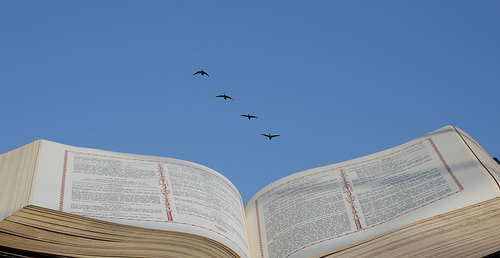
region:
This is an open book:
[1, 129, 496, 256]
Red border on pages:
[55, 140, 85, 222]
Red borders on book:
[52, 144, 467, 241]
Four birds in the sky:
[170, 58, 308, 173]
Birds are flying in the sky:
[182, 49, 293, 173]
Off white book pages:
[5, 140, 497, 257]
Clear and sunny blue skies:
[1, 0, 498, 192]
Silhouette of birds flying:
[195, 63, 305, 158]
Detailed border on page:
[155, 158, 187, 232]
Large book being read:
[6, 138, 498, 255]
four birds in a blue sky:
[63, 22, 400, 146]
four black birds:
[186, 56, 292, 151]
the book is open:
[2, 119, 498, 256]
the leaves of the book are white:
[1, 120, 498, 257]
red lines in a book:
[1, 120, 498, 255]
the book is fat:
[4, 121, 499, 256]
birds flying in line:
[191, 57, 282, 148]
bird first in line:
[189, 63, 213, 82]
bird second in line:
[209, 87, 237, 105]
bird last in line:
[256, 123, 281, 147]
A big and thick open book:
[0, 122, 498, 255]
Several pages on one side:
[320, 122, 497, 252]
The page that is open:
[26, 121, 496, 253]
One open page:
[27, 138, 249, 257]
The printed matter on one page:
[68, 152, 245, 248]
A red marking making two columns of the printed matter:
[156, 160, 171, 217]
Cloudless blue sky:
[0, 0, 497, 205]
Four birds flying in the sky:
[191, 66, 281, 138]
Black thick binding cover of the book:
[0, 245, 70, 256]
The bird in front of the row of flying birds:
[192, 66, 210, 76]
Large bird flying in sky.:
[183, 53, 213, 78]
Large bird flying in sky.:
[208, 84, 230, 99]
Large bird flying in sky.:
[238, 106, 261, 128]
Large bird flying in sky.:
[252, 118, 294, 157]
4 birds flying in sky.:
[173, 41, 303, 183]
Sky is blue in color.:
[335, 17, 440, 102]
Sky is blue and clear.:
[17, 24, 142, 131]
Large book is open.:
[27, 133, 467, 234]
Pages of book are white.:
[35, 146, 460, 238]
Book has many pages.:
[58, 178, 239, 253]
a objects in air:
[173, 58, 315, 159]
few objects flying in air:
[157, 41, 317, 183]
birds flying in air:
[181, 45, 300, 174]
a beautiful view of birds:
[146, 60, 333, 239]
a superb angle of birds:
[166, 50, 353, 182]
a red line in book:
[325, 149, 375, 249]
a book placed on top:
[18, 91, 491, 245]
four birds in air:
[183, 51, 318, 200]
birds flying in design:
[170, 33, 368, 193]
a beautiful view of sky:
[9, 5, 494, 128]